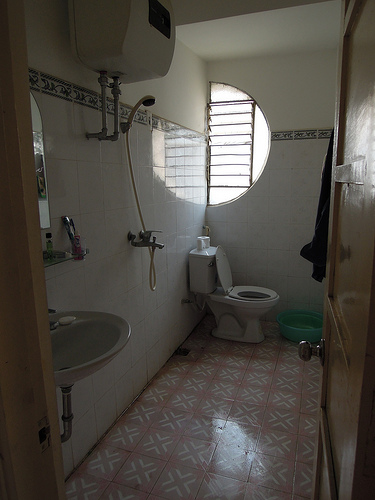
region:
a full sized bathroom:
[29, 22, 330, 495]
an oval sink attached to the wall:
[43, 300, 135, 455]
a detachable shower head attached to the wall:
[117, 91, 168, 148]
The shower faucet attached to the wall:
[126, 223, 165, 251]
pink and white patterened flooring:
[171, 379, 285, 498]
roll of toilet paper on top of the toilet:
[197, 236, 210, 251]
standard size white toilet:
[187, 228, 281, 345]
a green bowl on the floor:
[278, 306, 324, 343]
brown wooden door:
[334, 62, 374, 367]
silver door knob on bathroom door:
[296, 338, 327, 365]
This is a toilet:
[56, 51, 330, 498]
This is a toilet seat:
[214, 240, 281, 303]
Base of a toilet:
[216, 309, 282, 350]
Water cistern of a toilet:
[184, 223, 220, 307]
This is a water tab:
[122, 84, 183, 301]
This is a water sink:
[43, 298, 137, 396]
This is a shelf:
[60, 204, 94, 272]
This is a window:
[198, 71, 281, 208]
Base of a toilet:
[174, 306, 298, 367]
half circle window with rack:
[173, 62, 269, 222]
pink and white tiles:
[152, 345, 291, 463]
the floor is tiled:
[134, 353, 282, 446]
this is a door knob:
[291, 323, 340, 395]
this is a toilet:
[179, 221, 274, 356]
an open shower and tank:
[88, 31, 360, 445]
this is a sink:
[23, 275, 145, 387]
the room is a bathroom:
[31, 42, 337, 484]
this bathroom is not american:
[31, 79, 316, 475]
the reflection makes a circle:
[150, 63, 343, 209]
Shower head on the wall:
[122, 90, 156, 140]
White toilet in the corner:
[186, 241, 281, 344]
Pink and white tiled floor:
[61, 310, 324, 497]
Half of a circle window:
[203, 78, 271, 207]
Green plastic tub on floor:
[278, 303, 328, 345]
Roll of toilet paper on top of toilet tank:
[195, 234, 214, 251]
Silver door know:
[298, 336, 326, 367]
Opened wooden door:
[298, 0, 374, 495]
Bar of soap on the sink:
[59, 311, 78, 327]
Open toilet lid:
[214, 241, 234, 294]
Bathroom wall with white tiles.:
[54, 110, 203, 317]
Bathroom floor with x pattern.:
[188, 344, 299, 498]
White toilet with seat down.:
[190, 230, 284, 347]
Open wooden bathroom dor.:
[318, 158, 372, 499]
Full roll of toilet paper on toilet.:
[191, 233, 212, 252]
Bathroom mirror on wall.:
[30, 156, 55, 228]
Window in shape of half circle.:
[206, 81, 274, 207]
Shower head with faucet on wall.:
[118, 91, 159, 258]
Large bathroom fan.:
[65, 0, 174, 140]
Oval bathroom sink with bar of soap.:
[48, 281, 132, 441]